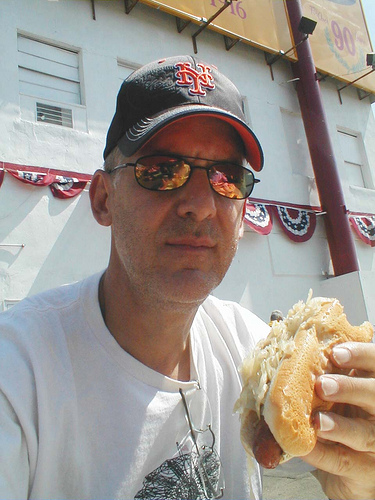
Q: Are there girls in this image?
A: No, there are no girls.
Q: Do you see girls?
A: No, there are no girls.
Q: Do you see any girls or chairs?
A: No, there are no girls or chairs.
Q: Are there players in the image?
A: No, there are no players.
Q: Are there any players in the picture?
A: No, there are no players.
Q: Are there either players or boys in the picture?
A: No, there are no players or boys.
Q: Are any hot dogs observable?
A: Yes, there is a hot dog.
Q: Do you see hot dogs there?
A: Yes, there is a hot dog.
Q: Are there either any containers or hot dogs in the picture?
A: Yes, there is a hot dog.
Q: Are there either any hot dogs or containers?
A: Yes, there is a hot dog.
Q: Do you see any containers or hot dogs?
A: Yes, there is a hot dog.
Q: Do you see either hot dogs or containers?
A: Yes, there is a hot dog.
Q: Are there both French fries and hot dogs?
A: No, there is a hot dog but no fries.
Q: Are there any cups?
A: No, there are no cups.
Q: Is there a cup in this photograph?
A: No, there are no cups.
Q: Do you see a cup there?
A: No, there are no cups.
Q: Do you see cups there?
A: No, there are no cups.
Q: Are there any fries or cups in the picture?
A: No, there are no cups or fries.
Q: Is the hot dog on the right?
A: Yes, the hot dog is on the right of the image.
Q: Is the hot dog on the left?
A: No, the hot dog is on the right of the image.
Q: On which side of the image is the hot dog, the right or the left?
A: The hot dog is on the right of the image.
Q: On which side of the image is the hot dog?
A: The hot dog is on the right of the image.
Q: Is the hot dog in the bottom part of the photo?
A: Yes, the hot dog is in the bottom of the image.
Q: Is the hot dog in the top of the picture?
A: No, the hot dog is in the bottom of the image.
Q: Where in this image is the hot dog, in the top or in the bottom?
A: The hot dog is in the bottom of the image.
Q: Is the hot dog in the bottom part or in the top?
A: The hot dog is in the bottom of the image.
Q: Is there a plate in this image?
A: No, there are no plates.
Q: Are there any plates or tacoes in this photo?
A: No, there are no plates or tacoes.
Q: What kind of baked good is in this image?
A: The baked good is a bun.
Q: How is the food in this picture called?
A: The food is a bun.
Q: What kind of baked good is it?
A: The food is a bun.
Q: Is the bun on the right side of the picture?
A: Yes, the bun is on the right of the image.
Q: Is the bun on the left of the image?
A: No, the bun is on the right of the image.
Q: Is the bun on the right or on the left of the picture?
A: The bun is on the right of the image.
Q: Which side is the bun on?
A: The bun is on the right of the image.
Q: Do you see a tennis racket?
A: No, there are no rackets.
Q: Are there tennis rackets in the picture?
A: No, there are no tennis rackets.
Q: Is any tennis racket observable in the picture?
A: No, there are no rackets.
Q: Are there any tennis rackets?
A: No, there are no tennis rackets.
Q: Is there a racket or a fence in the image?
A: No, there are no rackets or fences.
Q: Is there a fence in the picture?
A: No, there are no fences.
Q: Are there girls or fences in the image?
A: No, there are no fences or girls.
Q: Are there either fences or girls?
A: No, there are no fences or girls.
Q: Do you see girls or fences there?
A: No, there are no fences or girls.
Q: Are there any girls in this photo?
A: No, there are no girls.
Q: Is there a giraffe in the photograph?
A: No, there are no giraffes.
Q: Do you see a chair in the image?
A: No, there are no chairs.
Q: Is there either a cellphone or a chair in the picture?
A: No, there are no chairs or cell phones.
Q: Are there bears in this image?
A: No, there are no bears.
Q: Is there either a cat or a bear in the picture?
A: No, there are no bears or cats.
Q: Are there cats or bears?
A: No, there are no bears or cats.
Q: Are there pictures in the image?
A: No, there are no pictures.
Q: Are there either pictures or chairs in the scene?
A: No, there are no pictures or chairs.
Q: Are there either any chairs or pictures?
A: No, there are no pictures or chairs.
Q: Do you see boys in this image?
A: No, there are no boys.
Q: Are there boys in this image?
A: No, there are no boys.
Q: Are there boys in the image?
A: No, there are no boys.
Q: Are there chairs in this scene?
A: No, there are no chairs.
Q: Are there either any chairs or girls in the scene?
A: No, there are no chairs or girls.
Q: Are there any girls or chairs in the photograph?
A: No, there are no chairs or girls.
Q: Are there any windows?
A: Yes, there is a window.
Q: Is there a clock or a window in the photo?
A: Yes, there is a window.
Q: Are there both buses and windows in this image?
A: No, there is a window but no buses.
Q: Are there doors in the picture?
A: No, there are no doors.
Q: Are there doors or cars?
A: No, there are no doors or cars.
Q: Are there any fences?
A: No, there are no fences.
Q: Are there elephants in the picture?
A: No, there are no elephants.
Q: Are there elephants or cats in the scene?
A: No, there are no elephants or cats.